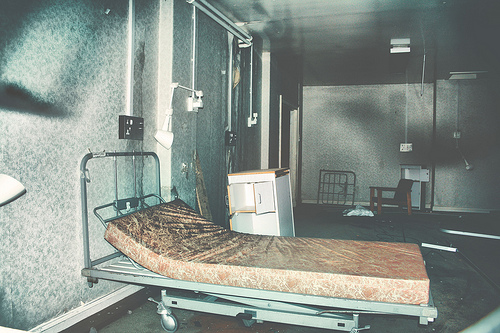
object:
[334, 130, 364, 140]
net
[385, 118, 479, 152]
court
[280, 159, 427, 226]
furniture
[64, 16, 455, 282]
room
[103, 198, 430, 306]
mattress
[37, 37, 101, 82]
wallpaper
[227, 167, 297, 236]
cabinet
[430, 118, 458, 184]
lamp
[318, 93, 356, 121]
wall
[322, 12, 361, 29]
ceiling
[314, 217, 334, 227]
floor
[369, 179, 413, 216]
chair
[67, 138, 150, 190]
frame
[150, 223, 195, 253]
marks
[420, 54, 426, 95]
pole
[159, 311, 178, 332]
wheel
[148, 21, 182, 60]
trim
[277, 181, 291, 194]
fridge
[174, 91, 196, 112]
globe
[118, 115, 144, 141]
socket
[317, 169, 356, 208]
table